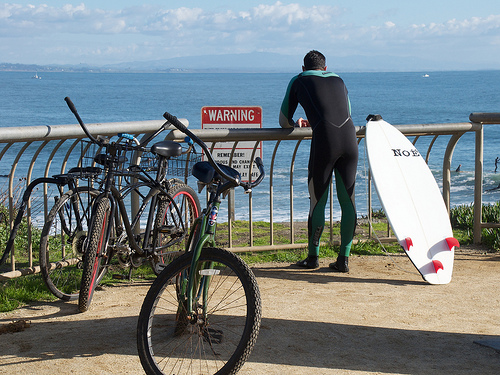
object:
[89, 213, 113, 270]
wheel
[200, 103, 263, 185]
warning sign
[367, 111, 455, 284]
surfboard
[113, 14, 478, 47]
sky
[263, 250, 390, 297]
shadow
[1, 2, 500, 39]
cloud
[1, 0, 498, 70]
sky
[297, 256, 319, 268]
black shoe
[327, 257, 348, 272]
black shoe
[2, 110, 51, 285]
rack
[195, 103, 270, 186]
sign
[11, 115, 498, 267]
fence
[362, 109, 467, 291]
surfboard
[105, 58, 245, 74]
mountains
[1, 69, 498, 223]
water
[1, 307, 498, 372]
shadow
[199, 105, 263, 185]
sign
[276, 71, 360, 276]
wet suit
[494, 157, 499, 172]
person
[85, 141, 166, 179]
basket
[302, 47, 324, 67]
hair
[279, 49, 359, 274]
man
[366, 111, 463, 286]
surfboard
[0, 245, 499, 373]
ground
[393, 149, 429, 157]
letters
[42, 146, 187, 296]
bikes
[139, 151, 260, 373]
bike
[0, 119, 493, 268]
railing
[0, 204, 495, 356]
beach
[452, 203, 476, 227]
area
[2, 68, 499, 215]
ocean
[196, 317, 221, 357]
kickstand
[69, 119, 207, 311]
bike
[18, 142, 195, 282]
bike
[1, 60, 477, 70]
shore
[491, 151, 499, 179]
surfer